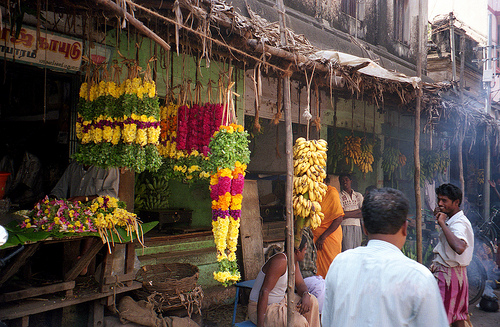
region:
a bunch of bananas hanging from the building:
[282, 135, 329, 235]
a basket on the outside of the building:
[137, 251, 194, 308]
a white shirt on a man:
[426, 210, 478, 275]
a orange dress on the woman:
[297, 184, 346, 272]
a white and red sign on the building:
[0, 22, 85, 74]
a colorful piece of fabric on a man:
[421, 266, 468, 324]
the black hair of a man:
[434, 178, 461, 200]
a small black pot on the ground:
[475, 291, 499, 314]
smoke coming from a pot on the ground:
[468, 248, 498, 303]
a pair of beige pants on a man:
[243, 290, 323, 323]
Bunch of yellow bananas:
[293, 112, 322, 244]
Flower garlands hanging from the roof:
[64, 46, 261, 273]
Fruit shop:
[274, 65, 476, 231]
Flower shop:
[8, 2, 268, 280]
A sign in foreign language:
[2, 15, 137, 85]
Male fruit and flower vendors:
[246, 157, 483, 302]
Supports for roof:
[248, 13, 458, 291]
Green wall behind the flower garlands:
[111, 29, 297, 309]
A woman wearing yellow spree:
[306, 162, 345, 265]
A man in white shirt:
[416, 176, 487, 278]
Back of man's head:
[356, 184, 416, 246]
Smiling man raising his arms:
[431, 178, 466, 221]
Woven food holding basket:
[130, 253, 213, 325]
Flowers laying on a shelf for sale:
[0, 186, 147, 248]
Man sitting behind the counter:
[41, 132, 132, 283]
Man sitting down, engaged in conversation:
[242, 228, 317, 325]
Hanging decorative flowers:
[197, 76, 269, 308]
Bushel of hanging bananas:
[275, 113, 334, 250]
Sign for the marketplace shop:
[0, 1, 105, 90]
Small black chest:
[135, 196, 202, 241]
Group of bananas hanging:
[285, 114, 338, 234]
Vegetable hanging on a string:
[210, 119, 262, 307]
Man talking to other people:
[426, 177, 496, 317]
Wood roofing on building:
[229, 12, 337, 102]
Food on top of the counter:
[29, 198, 153, 238]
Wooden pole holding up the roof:
[258, 70, 319, 323]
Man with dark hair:
[355, 184, 405, 271]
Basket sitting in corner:
[137, 252, 219, 322]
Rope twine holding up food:
[197, 46, 263, 113]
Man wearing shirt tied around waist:
[425, 264, 497, 316]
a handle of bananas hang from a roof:
[277, 40, 334, 249]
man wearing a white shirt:
[424, 178, 479, 322]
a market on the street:
[5, 5, 499, 325]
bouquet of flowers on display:
[7, 188, 144, 243]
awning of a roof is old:
[98, 0, 493, 105]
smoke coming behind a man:
[411, 62, 498, 295]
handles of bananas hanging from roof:
[326, 117, 486, 184]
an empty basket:
[131, 252, 206, 298]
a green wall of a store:
[106, 20, 246, 245]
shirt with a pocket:
[39, 156, 125, 208]